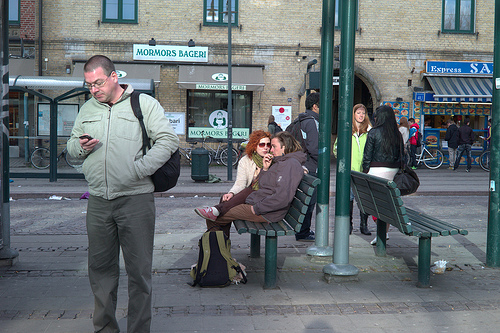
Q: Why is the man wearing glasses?
A: To see better.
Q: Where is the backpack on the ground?
A: Next to the people on the bench.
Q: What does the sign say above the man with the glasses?
A: Mormors bageri.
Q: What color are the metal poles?
A: Green.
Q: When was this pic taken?
A: During the daytime.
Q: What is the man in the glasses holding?
A: A cell phone.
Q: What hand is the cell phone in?
A: Right.